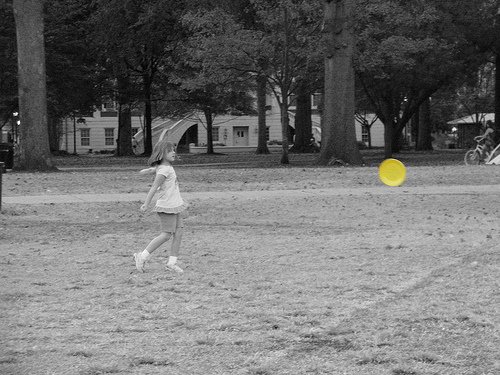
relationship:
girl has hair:
[133, 141, 187, 274] [144, 137, 178, 165]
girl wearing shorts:
[133, 141, 187, 271] [153, 212, 185, 234]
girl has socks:
[133, 141, 187, 274] [138, 250, 178, 267]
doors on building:
[217, 114, 255, 148] [65, 76, 292, 155]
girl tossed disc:
[133, 141, 187, 274] [372, 152, 412, 187]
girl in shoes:
[133, 141, 187, 274] [124, 242, 150, 275]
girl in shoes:
[133, 141, 187, 274] [162, 253, 191, 278]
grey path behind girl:
[57, 184, 132, 209] [133, 141, 187, 274]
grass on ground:
[207, 281, 427, 367] [80, 250, 246, 369]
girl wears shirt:
[133, 141, 187, 274] [153, 164, 190, 214]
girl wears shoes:
[133, 141, 187, 274] [95, 240, 179, 264]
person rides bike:
[476, 120, 498, 160] [464, 137, 499, 164]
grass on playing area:
[207, 281, 427, 367] [152, 272, 459, 373]